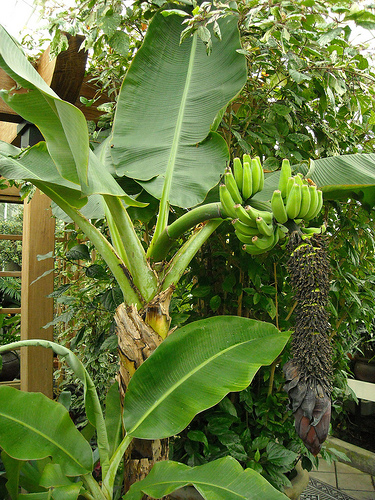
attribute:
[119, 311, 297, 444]
banana leaf — plant leaf, green, growing, large, gargantuan, single, small, big, rolled up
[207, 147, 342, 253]
bananas — hanging, green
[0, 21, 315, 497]
banana tree — young, banana plant, tall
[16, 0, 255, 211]
leaves — large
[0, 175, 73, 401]
structure — wooden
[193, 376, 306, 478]
plants — green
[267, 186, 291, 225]
banana — green, hanging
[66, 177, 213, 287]
branches — growing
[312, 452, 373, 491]
tile — outdoor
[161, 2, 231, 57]
leaves — small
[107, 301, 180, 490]
trunk — yellow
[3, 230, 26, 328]
rungs — wooden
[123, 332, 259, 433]
stripe — yellow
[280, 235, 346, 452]
banana flower — hanging, purple